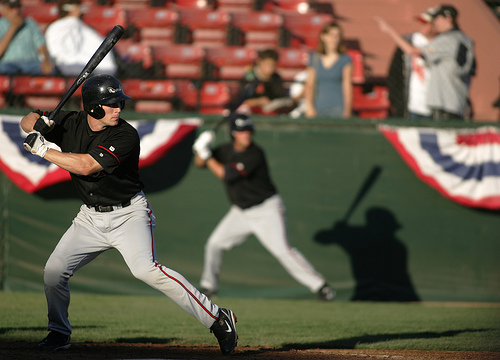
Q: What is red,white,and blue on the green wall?
A: Bunting.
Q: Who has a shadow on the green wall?
A: Batter.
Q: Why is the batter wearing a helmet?
A: Safety.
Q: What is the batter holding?
A: Baseball bat.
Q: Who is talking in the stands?
A: Two men.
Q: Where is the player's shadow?
A: On the wall.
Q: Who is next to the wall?
A: Another player.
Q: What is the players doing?
A: Preparing to bat.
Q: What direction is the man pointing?
A: To the left.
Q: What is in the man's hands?
A: A bat.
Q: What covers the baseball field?
A: Grass.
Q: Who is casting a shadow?
A: The man with a bat.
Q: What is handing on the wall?
A: Flags.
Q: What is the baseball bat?
A: Baseball player hands.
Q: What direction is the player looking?
A: To the right.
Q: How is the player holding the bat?
A: Both hands.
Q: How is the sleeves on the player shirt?
A: Short sleeve.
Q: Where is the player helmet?
A: On his head.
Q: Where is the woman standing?
A: In the crowd.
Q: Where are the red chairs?
A: Background.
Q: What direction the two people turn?
A: Left.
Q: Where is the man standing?
A: Batting base.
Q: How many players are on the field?
A: Two.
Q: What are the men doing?
A: Practicing their swing.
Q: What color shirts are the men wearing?
A: Black.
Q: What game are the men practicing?
A: Baseball.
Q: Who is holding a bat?
A: Two men.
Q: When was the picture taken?
A: During the day.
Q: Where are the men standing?
A: A baseball field.